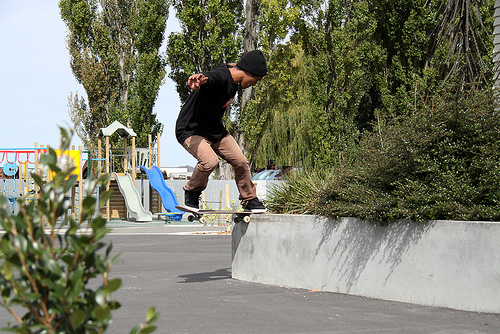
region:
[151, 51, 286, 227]
skateboarder performing tricks in park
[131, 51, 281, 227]
male skateboarder performing tricks in park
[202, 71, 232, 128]
male wearing black shirt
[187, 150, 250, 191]
young man wearing tan pants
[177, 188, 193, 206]
young man wearing black shoe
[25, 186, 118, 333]
bush with green leaves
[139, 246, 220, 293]
gray sidewalk in park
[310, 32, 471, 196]
trees and bushes with green leaves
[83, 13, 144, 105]
tree with green leaves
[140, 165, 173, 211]
blue slide in park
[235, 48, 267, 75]
a black knit cap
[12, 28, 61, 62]
a light blue sky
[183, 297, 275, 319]
a grey pavement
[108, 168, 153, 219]
a plastic grey slide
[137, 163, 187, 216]
a plastic blue slide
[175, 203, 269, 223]
a skateboard with white wheels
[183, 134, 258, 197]
a pair of brown pants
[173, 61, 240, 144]
a black tee shirt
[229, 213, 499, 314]
a concrete wall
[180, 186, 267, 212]
a pair of black gym shoes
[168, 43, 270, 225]
a skateboarder on a wall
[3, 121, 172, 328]
a green leafy bush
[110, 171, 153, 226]
a grey play slide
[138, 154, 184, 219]
a blue play slide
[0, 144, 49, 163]
a set of red monkey bars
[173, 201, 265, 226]
a brown skateboard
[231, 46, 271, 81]
a black stocking cap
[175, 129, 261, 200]
a pair of brown men's jeans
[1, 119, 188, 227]
children's playground equipment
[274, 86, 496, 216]
a large green bush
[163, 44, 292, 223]
a boy on a skateboard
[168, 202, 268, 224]
A skateboard with wheels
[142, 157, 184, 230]
A blue slide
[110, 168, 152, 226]
A white slide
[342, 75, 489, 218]
overgrown bushes with green leaves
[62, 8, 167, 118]
A tree in the background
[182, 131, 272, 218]
A boy wearing beige pants and black sneakers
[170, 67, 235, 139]
A boy wearing a black tee shirt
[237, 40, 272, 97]
A boy wearing a skull cap on his head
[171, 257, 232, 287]
TThe shadow of the boy on the skateboard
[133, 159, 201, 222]
The slide is blue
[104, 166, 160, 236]
The slide is grey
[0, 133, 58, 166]
The bars are red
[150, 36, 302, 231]
The guy is skateboarding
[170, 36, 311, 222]
The guy is wearing black shoes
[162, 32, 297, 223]
The guy is wearing a black hat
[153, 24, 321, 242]
The guy is wearing a black shirt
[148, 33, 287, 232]
The guy is wearing khaki pants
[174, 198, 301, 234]
The skateboard is on the wall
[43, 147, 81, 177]
Yellow wall of playground